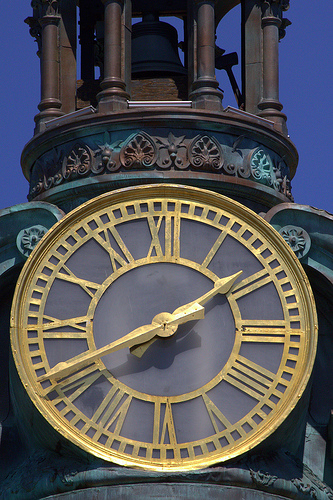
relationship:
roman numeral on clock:
[188, 214, 238, 269] [8, 160, 323, 488]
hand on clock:
[127, 269, 242, 357] [8, 183, 318, 472]